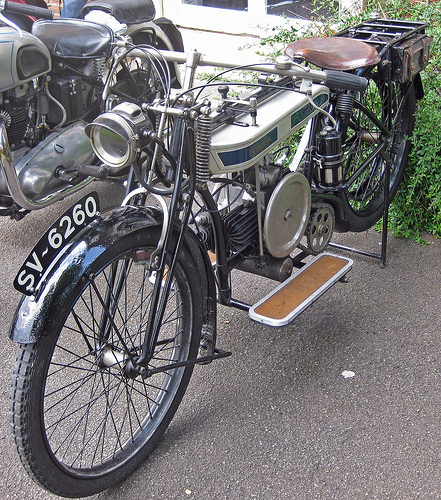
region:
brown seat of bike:
[282, 28, 368, 79]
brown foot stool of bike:
[241, 250, 353, 331]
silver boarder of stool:
[270, 295, 319, 326]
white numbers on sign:
[11, 201, 95, 284]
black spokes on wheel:
[59, 307, 115, 372]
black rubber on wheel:
[5, 353, 49, 437]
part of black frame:
[131, 183, 197, 364]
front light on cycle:
[80, 118, 131, 169]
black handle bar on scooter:
[317, 60, 368, 100]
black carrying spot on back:
[350, 2, 410, 53]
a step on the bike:
[244, 238, 366, 340]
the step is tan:
[246, 238, 362, 354]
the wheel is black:
[4, 233, 203, 468]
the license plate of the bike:
[3, 173, 117, 312]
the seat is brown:
[264, 21, 388, 88]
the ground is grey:
[219, 388, 414, 474]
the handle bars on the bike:
[108, 35, 323, 103]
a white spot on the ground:
[320, 354, 371, 398]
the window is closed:
[173, 3, 358, 45]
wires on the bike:
[118, 33, 267, 127]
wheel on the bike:
[32, 242, 202, 482]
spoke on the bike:
[105, 444, 128, 461]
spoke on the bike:
[83, 453, 98, 466]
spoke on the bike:
[121, 423, 144, 445]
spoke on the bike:
[141, 409, 155, 426]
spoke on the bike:
[159, 382, 170, 399]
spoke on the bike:
[172, 336, 183, 353]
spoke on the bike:
[42, 367, 51, 385]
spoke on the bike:
[58, 322, 70, 338]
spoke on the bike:
[40, 389, 55, 400]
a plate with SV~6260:
[7, 181, 118, 334]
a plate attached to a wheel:
[1, 187, 213, 487]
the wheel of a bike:
[8, 180, 247, 493]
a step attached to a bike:
[225, 215, 359, 337]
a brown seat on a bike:
[267, 23, 386, 116]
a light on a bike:
[65, 90, 178, 171]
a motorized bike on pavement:
[17, 7, 419, 485]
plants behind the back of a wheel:
[298, 13, 437, 246]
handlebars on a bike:
[26, 13, 388, 121]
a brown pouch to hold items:
[370, 19, 432, 105]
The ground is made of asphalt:
[246, 363, 416, 490]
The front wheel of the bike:
[4, 207, 218, 498]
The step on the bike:
[248, 245, 356, 342]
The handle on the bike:
[114, 34, 375, 102]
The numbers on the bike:
[6, 190, 106, 303]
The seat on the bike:
[285, 28, 383, 79]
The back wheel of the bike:
[315, 59, 420, 234]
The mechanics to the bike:
[210, 119, 349, 266]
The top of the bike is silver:
[199, 75, 337, 177]